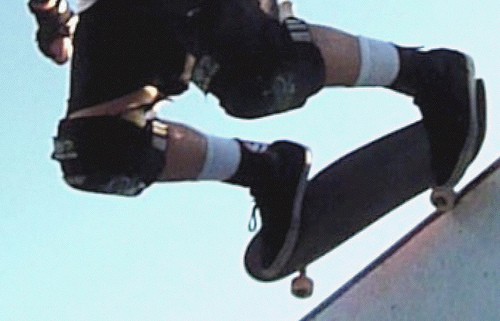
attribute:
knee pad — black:
[48, 96, 171, 198]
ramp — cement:
[347, 239, 469, 284]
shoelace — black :
[250, 205, 258, 233]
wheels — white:
[427, 186, 458, 211]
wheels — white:
[290, 273, 316, 298]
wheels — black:
[290, 182, 460, 297]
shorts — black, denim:
[67, 1, 259, 115]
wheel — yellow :
[287, 266, 318, 299]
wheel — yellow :
[415, 172, 482, 218]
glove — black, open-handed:
[29, 3, 78, 70]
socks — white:
[200, 35, 409, 182]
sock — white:
[195, 129, 240, 191]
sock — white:
[327, 15, 442, 138]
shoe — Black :
[411, 43, 477, 191]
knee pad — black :
[202, 23, 322, 117]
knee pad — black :
[54, 114, 164, 196]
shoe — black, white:
[246, 136, 312, 276]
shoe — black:
[228, 139, 310, 276]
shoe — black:
[252, 138, 311, 276]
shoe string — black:
[248, 200, 260, 232]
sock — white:
[348, 33, 407, 109]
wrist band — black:
[15, 1, 100, 75]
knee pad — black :
[54, 110, 169, 206]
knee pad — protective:
[210, 68, 293, 112]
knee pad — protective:
[45, 140, 117, 182]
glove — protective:
[28, 6, 66, 76]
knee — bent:
[56, 114, 151, 199]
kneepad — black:
[72, 139, 136, 219]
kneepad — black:
[223, 62, 285, 114]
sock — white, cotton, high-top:
[182, 133, 232, 182]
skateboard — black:
[234, 78, 490, 298]